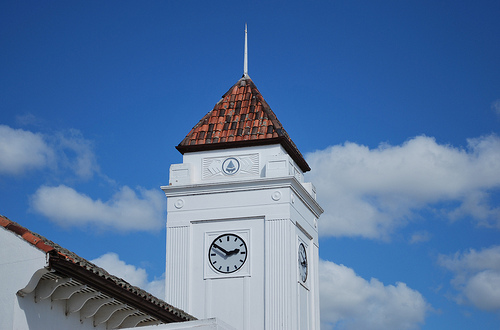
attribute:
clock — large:
[205, 230, 250, 278]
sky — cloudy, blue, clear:
[9, 7, 476, 317]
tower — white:
[152, 18, 322, 325]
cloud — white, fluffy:
[305, 127, 494, 243]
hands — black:
[214, 242, 243, 262]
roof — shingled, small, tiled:
[171, 74, 312, 152]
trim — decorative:
[169, 184, 287, 223]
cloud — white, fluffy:
[27, 181, 167, 239]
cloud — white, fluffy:
[2, 123, 53, 180]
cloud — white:
[322, 254, 433, 323]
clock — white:
[198, 231, 248, 276]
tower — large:
[154, 85, 329, 328]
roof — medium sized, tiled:
[0, 217, 199, 323]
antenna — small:
[236, 14, 256, 81]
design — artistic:
[221, 156, 245, 176]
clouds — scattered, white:
[322, 104, 486, 326]